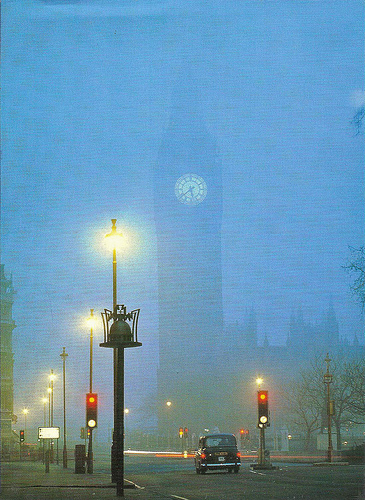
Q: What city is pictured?
A: London.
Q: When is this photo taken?
A: At night.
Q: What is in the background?
A: Big ben.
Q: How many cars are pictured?
A: One.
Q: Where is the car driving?
A: In the street.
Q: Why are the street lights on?
A: It is dark out.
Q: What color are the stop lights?
A: Red.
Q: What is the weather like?
A: Foggy.